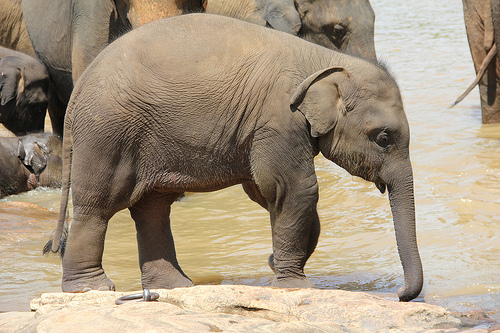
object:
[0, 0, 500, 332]
water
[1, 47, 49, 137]
elephant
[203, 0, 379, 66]
elephant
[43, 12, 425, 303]
elephant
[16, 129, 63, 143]
short hair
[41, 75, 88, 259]
tail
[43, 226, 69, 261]
hair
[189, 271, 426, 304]
shadow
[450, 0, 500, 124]
elephant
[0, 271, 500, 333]
rock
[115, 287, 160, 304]
excrement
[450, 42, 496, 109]
tail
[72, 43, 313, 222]
wrinkled skin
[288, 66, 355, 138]
large ear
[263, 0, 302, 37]
large ear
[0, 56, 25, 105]
large ear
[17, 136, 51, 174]
large ear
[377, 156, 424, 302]
trunk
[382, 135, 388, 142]
eye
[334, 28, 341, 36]
eye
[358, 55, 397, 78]
hair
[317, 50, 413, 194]
head